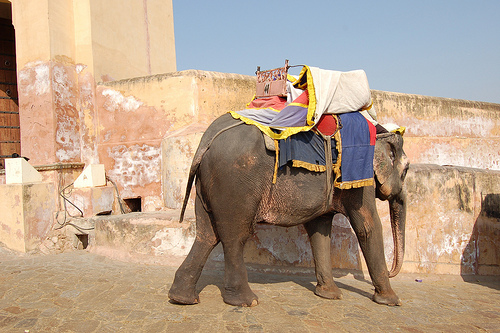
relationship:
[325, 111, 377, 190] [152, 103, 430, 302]
blankets on elepahant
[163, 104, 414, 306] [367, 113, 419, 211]
elephant has head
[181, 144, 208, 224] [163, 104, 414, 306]
elephant tail on elephant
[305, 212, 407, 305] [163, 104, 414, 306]
legs of elephant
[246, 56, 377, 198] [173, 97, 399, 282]
seat on elephant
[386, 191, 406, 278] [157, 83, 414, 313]
trunk on elephant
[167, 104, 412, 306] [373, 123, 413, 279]
elephant has head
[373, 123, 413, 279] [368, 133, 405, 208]
head has ear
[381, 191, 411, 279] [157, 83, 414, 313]
trunk of elephant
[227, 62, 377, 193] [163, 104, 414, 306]
blankets on elephant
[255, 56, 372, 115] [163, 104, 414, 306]
seat on elephant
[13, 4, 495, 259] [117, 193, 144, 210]
brick wall has opening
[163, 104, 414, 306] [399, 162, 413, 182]
elephant has eye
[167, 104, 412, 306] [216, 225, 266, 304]
elephant has leg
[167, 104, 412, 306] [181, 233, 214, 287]
elephant has leg